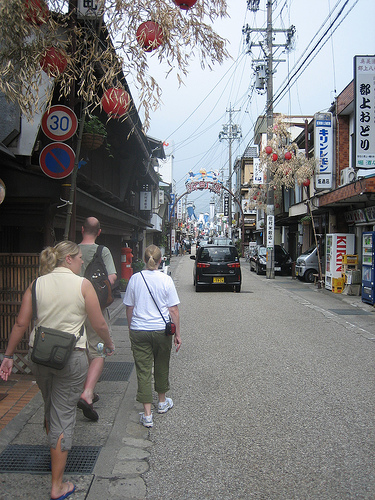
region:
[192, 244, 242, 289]
A black car on the road.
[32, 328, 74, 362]
A black bag in the photo.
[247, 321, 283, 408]
A road with tarmac.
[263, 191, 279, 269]
A power pole in the picture.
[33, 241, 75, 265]
Blonde hair in the picture.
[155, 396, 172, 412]
White sport shoes in the photo.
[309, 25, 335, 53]
Power cables in the picture.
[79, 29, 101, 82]
A tree in the picture.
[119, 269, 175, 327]
White t-shirt in the photo.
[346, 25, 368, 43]
Blue sky in the photo.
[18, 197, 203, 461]
people walking down the street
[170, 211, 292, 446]
a car driving down the street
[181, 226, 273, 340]
the car is black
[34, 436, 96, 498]
woman wearing flip flops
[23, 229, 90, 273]
the woman has blonde hair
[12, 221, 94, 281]
woman wearing a ponytail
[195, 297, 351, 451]
the street is grey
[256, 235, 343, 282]
cars parked on the sidewalk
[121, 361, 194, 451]
a woman wearing sneakers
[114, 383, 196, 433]
the sneakers are white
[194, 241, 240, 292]
A black van.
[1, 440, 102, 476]
A storm drain on the road.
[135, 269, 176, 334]
A small red and black crossbody bag.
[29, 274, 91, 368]
A dark colored crossbody bag.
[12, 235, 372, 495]
The street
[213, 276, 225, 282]
A yellow and black license plate.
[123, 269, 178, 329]
A white short sleeve shirt.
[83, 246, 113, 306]
A black backpack.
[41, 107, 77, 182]
Red, white, and blue traffic signs.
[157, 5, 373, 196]
Power lines above the street.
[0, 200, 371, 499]
three people walking down a narrow street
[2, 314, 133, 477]
grates set in the road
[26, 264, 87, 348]
woman wearing a collared, sleeveless shirt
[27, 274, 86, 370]
bag being carried behind woman's back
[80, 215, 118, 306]
backpack slung from man's right shoulder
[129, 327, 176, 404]
woman wearing short green pants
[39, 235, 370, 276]
woman is looking towards the opposite side of the road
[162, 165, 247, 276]
semicircular structure above street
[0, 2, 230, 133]
red ball-like objects set among tree branches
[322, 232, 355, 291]
a red and white vending machine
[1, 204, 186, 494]
the people are walking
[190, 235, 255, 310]
the car is black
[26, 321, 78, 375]
the purse is gray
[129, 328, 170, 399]
the pants are green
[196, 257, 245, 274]
the car has taillights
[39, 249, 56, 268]
the hair is blonde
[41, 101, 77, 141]
the sign is round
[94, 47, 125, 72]
the leaves are brown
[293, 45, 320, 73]
the wires are thick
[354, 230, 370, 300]
the vending machine is blue